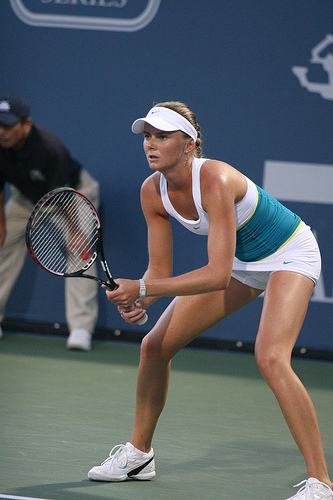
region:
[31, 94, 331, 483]
a woman playing tennis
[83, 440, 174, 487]
a white shoe with black stripe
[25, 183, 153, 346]
a black and red tennis racket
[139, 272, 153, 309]
a watch on the wrist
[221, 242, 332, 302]
a white skort with blue Nike symbol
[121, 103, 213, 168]
a white visor on head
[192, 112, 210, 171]
a braid in the back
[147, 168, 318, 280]
a white blue and yellow shirt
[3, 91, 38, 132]
a blue hat on his head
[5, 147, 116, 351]
black shirt and tan pants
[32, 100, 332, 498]
a female tennis player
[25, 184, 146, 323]
red and black tennis racket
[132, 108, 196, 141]
white visor with Nike swoosh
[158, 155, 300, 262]
white and green shirt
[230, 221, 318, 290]
the player's white tennis skirt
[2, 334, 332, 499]
the green tennis court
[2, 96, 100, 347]
line judge in a black shirt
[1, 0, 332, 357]
blue wall with white lettering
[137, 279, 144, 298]
a watch on the player's wrist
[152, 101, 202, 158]
the player's hair in a braided ponytail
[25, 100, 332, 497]
A woman playing tennis.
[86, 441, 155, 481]
A white tennis shoe with a black stripe on the side.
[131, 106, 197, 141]
A white sun visor on the woman's head.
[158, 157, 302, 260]
The woman is wearing a green, white and yellow shirt.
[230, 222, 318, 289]
The woman is wearing a white tennis skirt.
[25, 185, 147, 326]
The tennis racquet is being held with both hands.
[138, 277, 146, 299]
A watch on the woman's wrist.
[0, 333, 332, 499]
A green tennis court.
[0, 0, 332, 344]
A blue wall with white markings on it.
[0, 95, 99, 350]
A man in a blue hat is leaning against the blue wall.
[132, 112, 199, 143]
The visor the player is wearing.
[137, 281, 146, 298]
The watch on the player's wrist.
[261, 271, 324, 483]
The right leg of the player.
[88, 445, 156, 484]
The left sneaker of the player.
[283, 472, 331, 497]
The right sneaker of the player.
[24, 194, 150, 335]
The tennis racquet in the player's hand.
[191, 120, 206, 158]
The braid in the player's hair.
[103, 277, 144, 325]
The hands of the player.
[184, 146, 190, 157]
The earring in the player's ear.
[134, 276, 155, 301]
handwatch is silvery in color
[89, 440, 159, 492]
shoes are white in color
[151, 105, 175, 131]
cape is white in color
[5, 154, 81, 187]
t shirt is black in color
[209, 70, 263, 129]
wall is blue in color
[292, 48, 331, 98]
signs are written in white color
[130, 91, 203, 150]
a woman wearing a white hat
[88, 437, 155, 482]
a woman wearing white tennis shoes with a black stripe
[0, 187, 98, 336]
a man wearing tan pants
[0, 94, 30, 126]
a man wearing a black hat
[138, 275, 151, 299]
a woman wearing silver wrist watch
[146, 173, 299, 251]
a woman wearing a white and green shirt